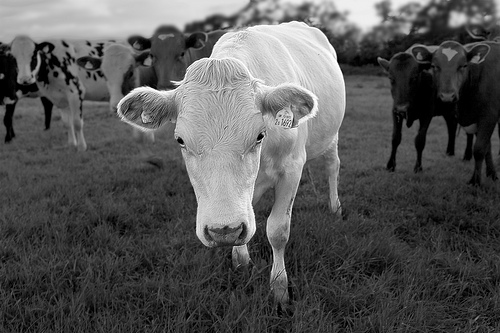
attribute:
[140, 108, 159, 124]
identification tab — small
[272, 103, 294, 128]
identification tab — small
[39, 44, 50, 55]
identification tab — small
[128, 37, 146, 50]
identification tab — small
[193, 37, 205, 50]
identification tab — small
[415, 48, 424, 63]
identification tab — small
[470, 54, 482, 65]
identification tab — small